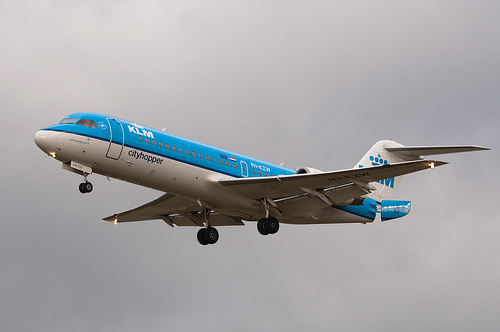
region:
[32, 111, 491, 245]
the airplane in the sky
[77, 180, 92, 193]
the wheel under the front of the plane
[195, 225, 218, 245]
the wheel under the middle of the plane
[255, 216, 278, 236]
the wheel under the middle of the plane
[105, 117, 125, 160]
the door on the plane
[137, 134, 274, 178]
the passenger windows on the plane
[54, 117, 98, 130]
the windows for the cockpit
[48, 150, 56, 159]
the light under the plane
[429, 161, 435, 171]
the light under the plane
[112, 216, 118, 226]
the light under the plane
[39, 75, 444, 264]
blue and white plane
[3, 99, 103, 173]
nose of the plane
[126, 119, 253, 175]
windows on side of plane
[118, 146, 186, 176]
the word "cityhopper"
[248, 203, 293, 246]
set of wheels under plane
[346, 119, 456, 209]
tail of the plane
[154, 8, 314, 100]
clouds in the sky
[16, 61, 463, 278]
plane in the air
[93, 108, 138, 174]
door of the plane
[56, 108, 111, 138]
front window of the plane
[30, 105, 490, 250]
A KLM aircraft in the air.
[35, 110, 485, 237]
The aircraft is blue and light grey colored.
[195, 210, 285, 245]
Airplane wheels under the wings.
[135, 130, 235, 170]
Airplane with many small windows.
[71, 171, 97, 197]
Front wheel of the aircraft still deployed.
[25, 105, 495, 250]
Airplane picking up altitude after take-off.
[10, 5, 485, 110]
Sky covered with heavy clouds.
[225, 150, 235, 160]
The Netherlands flag painted on the airplane.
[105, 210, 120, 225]
Light under the wing.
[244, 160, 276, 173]
Aircraft identification is next to the door.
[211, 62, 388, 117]
dark skies over head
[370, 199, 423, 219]
small logo on tail of plane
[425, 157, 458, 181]
light on side of plane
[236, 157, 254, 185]
door on side of plane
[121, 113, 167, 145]
name on side of plane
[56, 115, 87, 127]
window in front on plane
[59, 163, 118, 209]
wheel on plane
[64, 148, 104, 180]
frame holding wheel on plane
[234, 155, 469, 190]
wings on side of plane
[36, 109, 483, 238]
large plane in the sky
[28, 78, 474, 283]
Blue and white plane in the sky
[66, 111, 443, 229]
Blue and white plane in the sky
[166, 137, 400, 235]
Blue and white plane in the sky